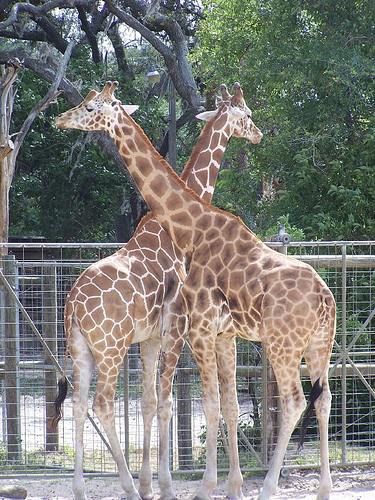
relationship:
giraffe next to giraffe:
[52, 81, 338, 499] [58, 83, 263, 499]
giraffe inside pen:
[52, 81, 338, 499] [0, 235, 374, 498]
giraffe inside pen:
[58, 83, 263, 499] [0, 235, 374, 498]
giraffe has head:
[52, 81, 338, 499] [52, 81, 140, 134]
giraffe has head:
[58, 83, 263, 499] [195, 81, 263, 146]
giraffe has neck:
[52, 81, 338, 499] [108, 117, 207, 264]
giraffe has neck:
[58, 83, 263, 499] [182, 128, 235, 204]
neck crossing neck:
[108, 117, 207, 264] [182, 128, 235, 204]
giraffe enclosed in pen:
[52, 81, 338, 499] [0, 235, 374, 498]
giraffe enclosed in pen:
[58, 83, 263, 499] [0, 235, 374, 498]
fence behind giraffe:
[0, 232, 373, 479] [52, 81, 338, 499]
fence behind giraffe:
[0, 232, 373, 479] [58, 83, 263, 499]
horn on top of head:
[102, 81, 112, 97] [52, 81, 140, 134]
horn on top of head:
[111, 81, 120, 95] [52, 81, 140, 134]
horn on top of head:
[222, 84, 230, 100] [195, 81, 263, 146]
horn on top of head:
[232, 83, 244, 100] [195, 81, 263, 146]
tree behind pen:
[0, 2, 217, 242] [0, 235, 374, 498]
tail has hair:
[296, 303, 332, 453] [297, 381, 324, 454]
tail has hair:
[51, 302, 72, 430] [52, 379, 69, 427]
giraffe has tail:
[52, 81, 338, 499] [296, 303, 332, 453]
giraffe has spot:
[52, 81, 338, 499] [134, 155, 152, 177]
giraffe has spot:
[52, 81, 338, 499] [165, 194, 188, 211]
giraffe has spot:
[52, 81, 338, 499] [173, 227, 193, 249]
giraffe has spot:
[52, 81, 338, 499] [220, 243, 236, 268]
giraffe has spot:
[52, 81, 338, 499] [229, 270, 247, 286]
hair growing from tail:
[52, 379, 69, 427] [51, 302, 72, 430]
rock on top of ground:
[0, 488, 27, 499] [0, 351, 374, 499]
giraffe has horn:
[52, 81, 338, 499] [102, 81, 112, 97]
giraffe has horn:
[52, 81, 338, 499] [111, 81, 120, 95]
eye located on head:
[84, 106, 93, 113] [52, 81, 140, 134]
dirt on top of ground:
[0, 395, 374, 499] [0, 351, 374, 499]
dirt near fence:
[0, 395, 374, 499] [0, 232, 373, 479]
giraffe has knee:
[58, 83, 263, 499] [157, 396, 173, 421]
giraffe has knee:
[58, 83, 263, 499] [141, 396, 157, 420]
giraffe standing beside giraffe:
[52, 81, 338, 499] [58, 83, 263, 499]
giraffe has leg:
[52, 81, 338, 499] [189, 326, 220, 499]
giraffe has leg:
[52, 81, 338, 499] [216, 335, 243, 499]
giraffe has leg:
[52, 81, 338, 499] [261, 346, 306, 499]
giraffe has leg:
[52, 81, 338, 499] [305, 353, 334, 499]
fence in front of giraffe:
[0, 232, 373, 479] [52, 81, 338, 499]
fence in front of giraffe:
[0, 232, 373, 479] [58, 83, 263, 499]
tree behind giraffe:
[0, 2, 217, 242] [52, 81, 338, 499]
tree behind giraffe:
[0, 0, 375, 242] [52, 81, 338, 499]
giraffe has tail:
[58, 83, 263, 499] [51, 302, 72, 430]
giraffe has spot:
[58, 83, 263, 499] [208, 133, 220, 150]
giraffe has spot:
[58, 83, 263, 499] [127, 294, 148, 323]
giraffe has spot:
[58, 83, 263, 499] [91, 307, 105, 327]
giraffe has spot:
[58, 83, 263, 499] [91, 273, 113, 292]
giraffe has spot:
[58, 83, 263, 499] [144, 221, 161, 235]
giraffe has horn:
[58, 83, 263, 499] [222, 84, 230, 100]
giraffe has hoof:
[52, 81, 338, 499] [225, 496, 242, 499]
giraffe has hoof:
[52, 81, 338, 499] [189, 495, 218, 499]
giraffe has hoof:
[58, 83, 263, 499] [158, 495, 179, 499]